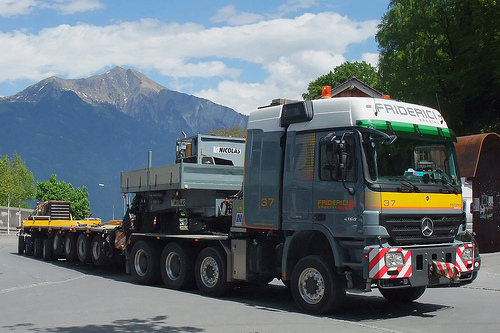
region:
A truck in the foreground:
[13, 69, 485, 321]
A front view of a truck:
[339, 88, 488, 313]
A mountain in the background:
[0, 58, 250, 202]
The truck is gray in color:
[236, 85, 490, 310]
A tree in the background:
[300, 42, 499, 140]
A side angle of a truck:
[235, 101, 369, 310]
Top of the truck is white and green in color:
[243, 92, 453, 147]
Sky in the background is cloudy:
[0, 1, 390, 112]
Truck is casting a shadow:
[11, 241, 456, 324]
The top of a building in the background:
[313, 73, 385, 103]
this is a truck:
[16, 79, 478, 301]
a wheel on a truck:
[284, 255, 345, 330]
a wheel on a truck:
[191, 240, 226, 292]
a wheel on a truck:
[152, 246, 191, 286]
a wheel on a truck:
[122, 240, 162, 275]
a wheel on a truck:
[84, 229, 116, 264]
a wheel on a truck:
[76, 223, 94, 263]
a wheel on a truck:
[58, 231, 81, 255]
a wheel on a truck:
[43, 229, 64, 259]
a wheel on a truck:
[35, 231, 57, 254]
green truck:
[244, 71, 477, 320]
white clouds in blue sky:
[12, 7, 47, 40]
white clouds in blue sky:
[3, 48, 38, 73]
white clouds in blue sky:
[21, 14, 58, 56]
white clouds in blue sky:
[57, 24, 83, 68]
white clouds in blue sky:
[91, 8, 121, 54]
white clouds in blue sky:
[139, 7, 172, 57]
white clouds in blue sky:
[182, 12, 248, 63]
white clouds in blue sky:
[221, 44, 265, 97]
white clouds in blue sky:
[258, 23, 315, 74]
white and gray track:
[238, 85, 477, 319]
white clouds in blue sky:
[40, 6, 89, 66]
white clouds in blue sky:
[149, 12, 191, 67]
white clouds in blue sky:
[199, 39, 251, 85]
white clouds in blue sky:
[234, 25, 289, 72]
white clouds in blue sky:
[281, 16, 342, 44]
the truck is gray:
[244, 114, 435, 296]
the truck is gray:
[310, 103, 479, 330]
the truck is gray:
[288, 77, 401, 324]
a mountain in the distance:
[17, 47, 124, 178]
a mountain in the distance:
[94, 56, 226, 153]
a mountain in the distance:
[15, 65, 201, 186]